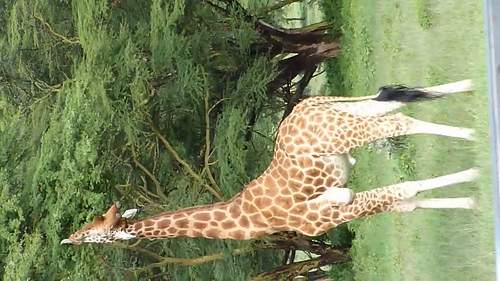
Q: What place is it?
A: It is a field.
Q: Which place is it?
A: It is a field.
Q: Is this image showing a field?
A: Yes, it is showing a field.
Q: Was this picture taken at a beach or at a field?
A: It was taken at a field.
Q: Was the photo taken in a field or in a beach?
A: It was taken at a field.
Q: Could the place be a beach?
A: No, it is a field.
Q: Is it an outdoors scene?
A: Yes, it is outdoors.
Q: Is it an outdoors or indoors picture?
A: It is outdoors.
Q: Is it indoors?
A: No, it is outdoors.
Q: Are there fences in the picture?
A: No, there are no fences.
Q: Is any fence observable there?
A: No, there are no fences.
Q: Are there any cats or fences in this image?
A: No, there are no fences or cats.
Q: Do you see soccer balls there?
A: No, there are no soccer balls.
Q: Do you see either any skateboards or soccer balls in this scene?
A: No, there are no soccer balls or skateboards.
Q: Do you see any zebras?
A: No, there are no zebras.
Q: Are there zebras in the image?
A: No, there are no zebras.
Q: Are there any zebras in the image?
A: No, there are no zebras.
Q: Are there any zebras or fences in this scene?
A: No, there are no zebras or fences.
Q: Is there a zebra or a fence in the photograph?
A: No, there are no zebras or fences.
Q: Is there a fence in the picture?
A: No, there are no fences.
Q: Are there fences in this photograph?
A: No, there are no fences.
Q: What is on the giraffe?
A: The spots are on the giraffe.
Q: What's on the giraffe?
A: The spots are on the giraffe.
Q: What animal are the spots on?
A: The spots are on the giraffe.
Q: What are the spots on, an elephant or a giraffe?
A: The spots are on a giraffe.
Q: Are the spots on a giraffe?
A: Yes, the spots are on a giraffe.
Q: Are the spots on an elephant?
A: No, the spots are on a giraffe.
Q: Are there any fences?
A: No, there are no fences.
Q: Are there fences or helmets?
A: No, there are no fences or helmets.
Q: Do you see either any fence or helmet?
A: No, there are no fences or helmets.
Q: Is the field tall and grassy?
A: Yes, the field is tall and grassy.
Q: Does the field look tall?
A: Yes, the field is tall.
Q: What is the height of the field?
A: The field is tall.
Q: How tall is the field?
A: The field is tall.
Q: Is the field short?
A: No, the field is tall.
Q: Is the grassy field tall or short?
A: The field is tall.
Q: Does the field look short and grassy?
A: No, the field is grassy but tall.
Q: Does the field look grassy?
A: Yes, the field is grassy.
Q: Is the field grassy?
A: Yes, the field is grassy.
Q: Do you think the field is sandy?
A: No, the field is grassy.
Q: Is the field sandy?
A: No, the field is grassy.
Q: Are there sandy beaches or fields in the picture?
A: No, there is a field but it is grassy.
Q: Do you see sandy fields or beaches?
A: No, there is a field but it is grassy.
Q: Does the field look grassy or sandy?
A: The field is grassy.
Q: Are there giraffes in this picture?
A: Yes, there is a giraffe.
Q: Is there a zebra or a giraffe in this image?
A: Yes, there is a giraffe.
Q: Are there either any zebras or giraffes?
A: Yes, there is a giraffe.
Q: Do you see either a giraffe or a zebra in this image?
A: Yes, there is a giraffe.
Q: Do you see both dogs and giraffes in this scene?
A: No, there is a giraffe but no dogs.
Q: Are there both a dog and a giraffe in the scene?
A: No, there is a giraffe but no dogs.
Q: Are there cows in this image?
A: No, there are no cows.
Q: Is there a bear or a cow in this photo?
A: No, there are no cows or bears.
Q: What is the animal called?
A: The animal is a giraffe.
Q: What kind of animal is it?
A: The animal is a giraffe.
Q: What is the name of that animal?
A: That is a giraffe.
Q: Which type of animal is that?
A: That is a giraffe.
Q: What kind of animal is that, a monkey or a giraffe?
A: That is a giraffe.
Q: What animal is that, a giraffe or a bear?
A: That is a giraffe.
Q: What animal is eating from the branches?
A: The giraffe is eating from the branches.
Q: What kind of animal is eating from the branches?
A: The animal is a giraffe.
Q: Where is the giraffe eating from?
A: The giraffe is eating from the branches.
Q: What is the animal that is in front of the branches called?
A: The animal is a giraffe.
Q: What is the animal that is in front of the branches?
A: The animal is a giraffe.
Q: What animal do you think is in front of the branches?
A: The animal is a giraffe.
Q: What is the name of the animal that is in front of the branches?
A: The animal is a giraffe.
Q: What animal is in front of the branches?
A: The animal is a giraffe.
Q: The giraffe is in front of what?
A: The giraffe is in front of the branches.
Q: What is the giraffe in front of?
A: The giraffe is in front of the branches.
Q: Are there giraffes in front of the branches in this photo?
A: Yes, there is a giraffe in front of the branches.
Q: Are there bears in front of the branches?
A: No, there is a giraffe in front of the branches.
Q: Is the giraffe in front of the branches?
A: Yes, the giraffe is in front of the branches.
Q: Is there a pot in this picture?
A: No, there are no pots.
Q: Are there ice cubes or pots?
A: No, there are no pots or ice cubes.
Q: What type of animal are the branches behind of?
A: The branches are behind the giraffe.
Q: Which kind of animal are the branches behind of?
A: The branches are behind the giraffe.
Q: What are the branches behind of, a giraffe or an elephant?
A: The branches are behind a giraffe.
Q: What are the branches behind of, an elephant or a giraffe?
A: The branches are behind a giraffe.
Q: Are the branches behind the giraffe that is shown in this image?
A: Yes, the branches are behind the giraffe.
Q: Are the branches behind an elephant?
A: No, the branches are behind the giraffe.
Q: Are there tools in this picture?
A: No, there are no tools.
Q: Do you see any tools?
A: No, there are no tools.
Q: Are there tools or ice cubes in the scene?
A: No, there are no tools or ice cubes.